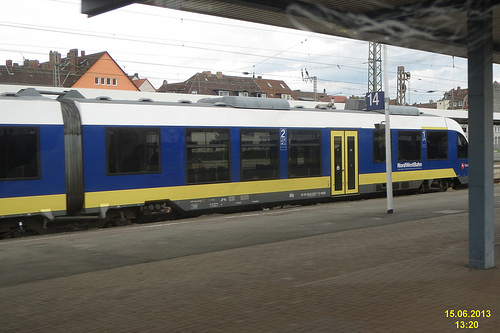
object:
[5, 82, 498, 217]
train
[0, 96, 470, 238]
train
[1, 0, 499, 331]
train station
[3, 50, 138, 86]
roof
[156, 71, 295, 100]
building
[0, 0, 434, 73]
clouds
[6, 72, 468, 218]
bus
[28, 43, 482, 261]
train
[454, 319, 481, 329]
time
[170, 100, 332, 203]
train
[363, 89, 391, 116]
sign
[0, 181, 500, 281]
ground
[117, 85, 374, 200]
train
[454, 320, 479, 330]
date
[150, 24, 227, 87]
wires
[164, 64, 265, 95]
roof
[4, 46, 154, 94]
house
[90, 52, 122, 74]
orange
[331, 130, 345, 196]
door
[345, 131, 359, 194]
door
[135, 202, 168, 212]
wheel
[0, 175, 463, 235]
wheels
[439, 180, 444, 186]
part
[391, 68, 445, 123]
tower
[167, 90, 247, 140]
wall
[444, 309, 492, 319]
date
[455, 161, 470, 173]
sticker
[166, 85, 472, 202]
train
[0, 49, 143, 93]
building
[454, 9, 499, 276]
pole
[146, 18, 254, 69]
sky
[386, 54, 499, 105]
clouds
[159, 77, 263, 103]
house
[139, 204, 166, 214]
part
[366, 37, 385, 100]
tower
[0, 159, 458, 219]
stripe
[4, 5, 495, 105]
sky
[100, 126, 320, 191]
windows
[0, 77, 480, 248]
train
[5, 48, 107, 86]
roof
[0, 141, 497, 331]
land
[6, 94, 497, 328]
land